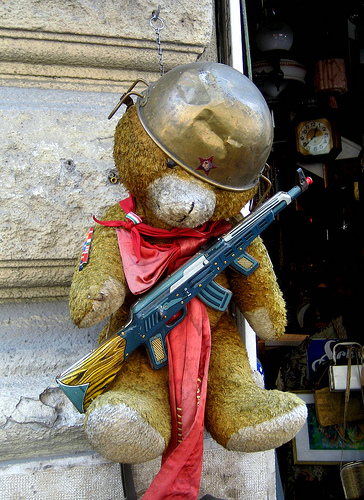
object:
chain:
[149, 13, 166, 75]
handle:
[107, 78, 149, 121]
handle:
[249, 163, 273, 213]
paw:
[67, 304, 105, 329]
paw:
[257, 320, 288, 342]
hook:
[147, 5, 162, 23]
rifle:
[51, 165, 318, 407]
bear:
[68, 60, 309, 464]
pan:
[107, 61, 272, 212]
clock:
[295, 118, 333, 155]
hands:
[296, 118, 333, 153]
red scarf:
[89, 197, 220, 500]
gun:
[54, 167, 317, 416]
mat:
[200, 459, 274, 496]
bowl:
[107, 60, 276, 215]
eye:
[167, 161, 177, 168]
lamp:
[251, 1, 297, 91]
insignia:
[196, 155, 219, 177]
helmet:
[107, 60, 271, 212]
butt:
[54, 329, 130, 414]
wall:
[28, 93, 85, 191]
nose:
[168, 201, 200, 224]